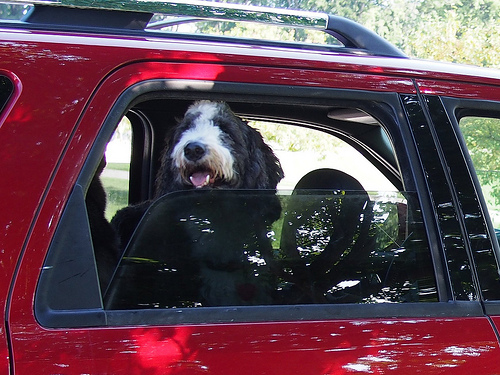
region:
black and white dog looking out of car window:
[11, 18, 474, 362]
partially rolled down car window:
[63, 185, 435, 312]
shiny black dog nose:
[182, 140, 206, 167]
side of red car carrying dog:
[6, 1, 486, 362]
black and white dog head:
[154, 97, 280, 187]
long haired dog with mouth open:
[166, 99, 244, 193]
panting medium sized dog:
[163, 95, 261, 193]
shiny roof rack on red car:
[16, 1, 420, 62]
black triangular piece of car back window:
[31, 180, 110, 327]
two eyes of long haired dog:
[174, 119, 235, 136]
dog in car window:
[144, 89, 317, 251]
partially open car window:
[327, 88, 412, 216]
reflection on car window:
[234, 205, 346, 295]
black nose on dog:
[174, 138, 219, 168]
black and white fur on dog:
[162, 91, 260, 179]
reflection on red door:
[352, 314, 479, 371]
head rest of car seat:
[284, 157, 376, 256]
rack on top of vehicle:
[228, 4, 352, 41]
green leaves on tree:
[472, 121, 494, 163]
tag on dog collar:
[208, 245, 265, 305]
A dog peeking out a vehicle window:
[153, 93, 287, 195]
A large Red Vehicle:
[1, 0, 498, 372]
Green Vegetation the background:
[373, 0, 492, 65]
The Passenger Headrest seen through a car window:
[276, 170, 377, 267]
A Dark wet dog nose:
[180, 132, 213, 164]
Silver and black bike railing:
[85, 0, 327, 35]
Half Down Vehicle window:
[101, 186, 458, 310]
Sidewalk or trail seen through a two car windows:
[101, 162, 133, 187]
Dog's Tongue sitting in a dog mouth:
[182, 167, 224, 192]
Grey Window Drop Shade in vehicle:
[328, 110, 383, 122]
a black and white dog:
[152, 96, 283, 305]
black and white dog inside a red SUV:
[1, 1, 498, 373]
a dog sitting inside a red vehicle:
[1, 2, 498, 374]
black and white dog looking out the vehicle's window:
[100, 80, 441, 307]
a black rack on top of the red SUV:
[0, 1, 412, 59]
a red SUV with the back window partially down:
[1, 0, 498, 372]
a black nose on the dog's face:
[183, 140, 203, 162]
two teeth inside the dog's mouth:
[183, 165, 213, 189]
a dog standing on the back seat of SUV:
[0, 1, 497, 373]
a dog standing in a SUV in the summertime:
[110, 100, 285, 305]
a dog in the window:
[66, 59, 323, 279]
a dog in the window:
[125, 138, 264, 364]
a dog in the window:
[84, 113, 351, 373]